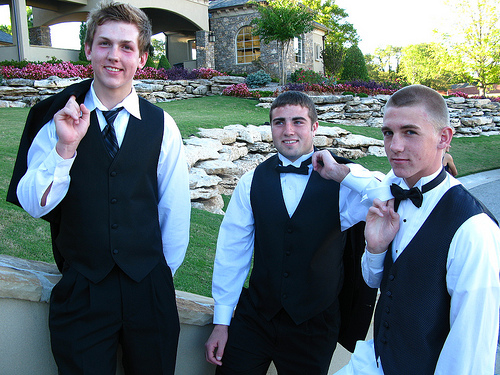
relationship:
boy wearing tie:
[331, 84, 498, 375] [390, 173, 454, 207]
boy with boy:
[331, 84, 498, 375] [204, 89, 387, 375]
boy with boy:
[204, 89, 387, 375] [15, 2, 191, 375]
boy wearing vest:
[204, 89, 387, 375] [221, 63, 376, 370]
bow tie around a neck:
[274, 147, 317, 175] [252, 139, 327, 168]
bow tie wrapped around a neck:
[274, 147, 317, 175] [268, 132, 323, 184]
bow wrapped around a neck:
[390, 183, 424, 209] [384, 160, 442, 203]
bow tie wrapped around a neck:
[390, 167, 447, 209] [395, 167, 447, 201]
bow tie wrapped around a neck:
[274, 147, 317, 175] [277, 153, 317, 169]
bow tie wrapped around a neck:
[385, 167, 454, 204] [388, 157, 448, 190]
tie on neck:
[92, 107, 122, 143] [84, 87, 133, 121]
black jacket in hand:
[0, 71, 93, 207] [48, 93, 97, 154]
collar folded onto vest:
[84, 87, 144, 120] [49, 97, 166, 284]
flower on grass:
[222, 83, 251, 97] [2, 93, 498, 302]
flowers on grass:
[2, 63, 262, 103] [2, 93, 498, 302]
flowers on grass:
[162, 58, 222, 80] [2, 93, 498, 302]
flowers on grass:
[273, 76, 452, 97] [2, 93, 498, 302]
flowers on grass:
[352, 80, 479, 105] [2, 93, 498, 302]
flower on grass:
[222, 82, 233, 93] [3, 76, 498, 336]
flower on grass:
[147, 67, 157, 76] [3, 76, 498, 336]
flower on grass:
[312, 82, 321, 88] [3, 76, 498, 336]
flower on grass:
[342, 82, 353, 92] [3, 76, 498, 336]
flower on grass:
[53, 64, 60, 73] [3, 76, 498, 336]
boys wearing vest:
[203, 83, 498, 373] [373, 183, 499, 373]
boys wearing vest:
[203, 83, 498, 373] [248, 152, 343, 334]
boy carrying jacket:
[5, 2, 191, 374] [7, 80, 93, 204]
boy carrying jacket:
[203, 89, 387, 374] [331, 156, 376, 354]